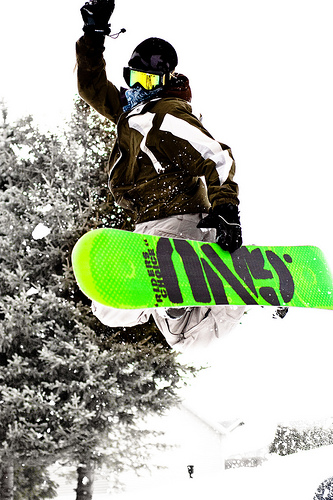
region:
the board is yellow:
[99, 242, 139, 297]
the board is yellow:
[104, 241, 116, 259]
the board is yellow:
[98, 251, 202, 352]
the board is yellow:
[101, 230, 165, 342]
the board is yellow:
[101, 251, 133, 279]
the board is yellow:
[94, 266, 130, 295]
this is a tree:
[8, 297, 66, 458]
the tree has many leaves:
[10, 318, 50, 416]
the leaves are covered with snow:
[21, 304, 64, 394]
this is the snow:
[211, 479, 272, 494]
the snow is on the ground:
[221, 474, 284, 495]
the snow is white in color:
[240, 469, 291, 497]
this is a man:
[64, 0, 331, 345]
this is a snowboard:
[71, 225, 330, 311]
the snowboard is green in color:
[88, 248, 117, 279]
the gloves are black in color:
[89, 0, 105, 18]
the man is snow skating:
[74, 29, 259, 362]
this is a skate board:
[183, 252, 257, 297]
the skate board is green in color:
[91, 243, 148, 299]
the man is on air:
[91, 30, 266, 371]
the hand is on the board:
[198, 202, 237, 266]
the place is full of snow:
[220, 366, 271, 414]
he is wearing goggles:
[123, 71, 158, 83]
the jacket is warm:
[112, 122, 194, 211]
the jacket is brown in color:
[138, 127, 200, 182]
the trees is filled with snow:
[12, 326, 123, 408]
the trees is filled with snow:
[33, 371, 179, 473]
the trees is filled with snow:
[33, 355, 124, 428]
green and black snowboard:
[119, 235, 305, 317]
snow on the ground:
[219, 446, 279, 497]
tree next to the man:
[24, 349, 96, 423]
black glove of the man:
[206, 189, 259, 252]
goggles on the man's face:
[127, 54, 175, 93]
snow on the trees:
[2, 173, 83, 249]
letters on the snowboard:
[157, 240, 294, 308]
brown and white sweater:
[101, 92, 228, 209]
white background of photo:
[177, 42, 266, 137]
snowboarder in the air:
[60, 76, 285, 293]